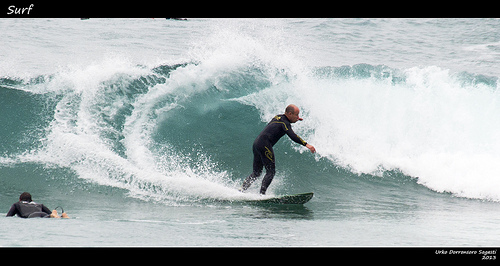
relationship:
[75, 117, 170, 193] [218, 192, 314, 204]
wake created by board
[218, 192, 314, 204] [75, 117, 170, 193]
board in wake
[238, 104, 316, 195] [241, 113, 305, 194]
man wearing wet suit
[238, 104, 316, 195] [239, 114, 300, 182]
man wearing a wetsuit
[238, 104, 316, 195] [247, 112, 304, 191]
man wearing wetsuit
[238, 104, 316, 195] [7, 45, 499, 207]
man riding wave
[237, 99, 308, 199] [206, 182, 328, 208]
man on surfboard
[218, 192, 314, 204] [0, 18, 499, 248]
board in water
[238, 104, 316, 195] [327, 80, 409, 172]
man on ocean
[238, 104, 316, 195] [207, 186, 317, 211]
man on surfboard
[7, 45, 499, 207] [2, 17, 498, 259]
wave on ocean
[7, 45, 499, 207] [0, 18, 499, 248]
wave in water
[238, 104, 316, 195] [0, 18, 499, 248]
man in water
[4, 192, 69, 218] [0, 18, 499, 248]
man lying in water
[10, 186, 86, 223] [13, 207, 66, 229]
man lying on board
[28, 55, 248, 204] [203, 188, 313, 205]
water trail behind surfboard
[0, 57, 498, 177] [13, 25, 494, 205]
waves are water